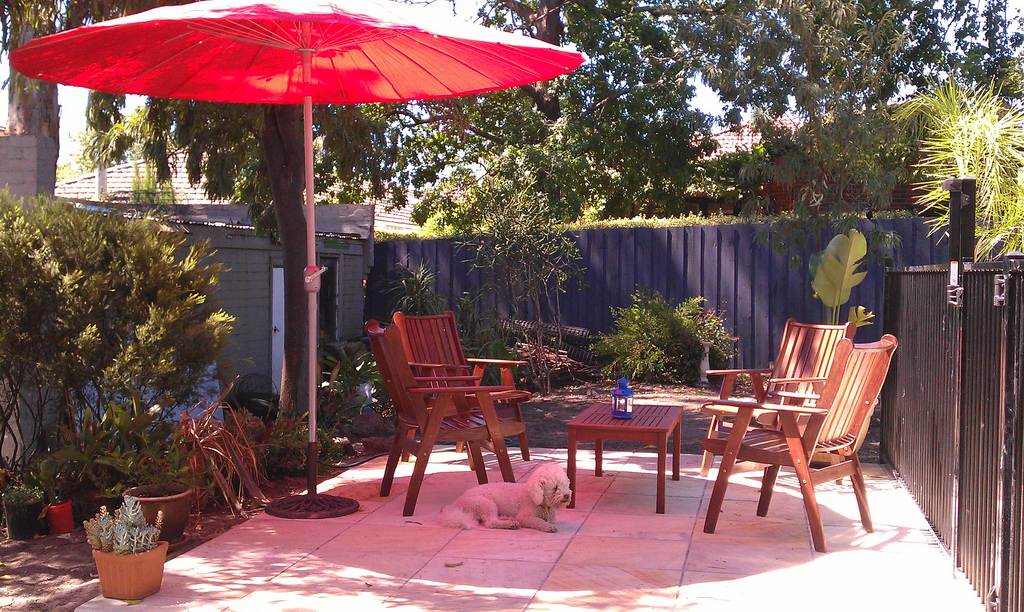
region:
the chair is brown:
[785, 330, 903, 539]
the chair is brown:
[703, 304, 840, 400]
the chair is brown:
[394, 306, 525, 371]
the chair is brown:
[353, 314, 440, 523]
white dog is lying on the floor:
[429, 448, 592, 546]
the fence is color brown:
[887, 227, 1020, 610]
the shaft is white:
[261, 30, 367, 524]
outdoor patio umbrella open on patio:
[8, 2, 590, 528]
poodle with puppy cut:
[439, 458, 580, 538]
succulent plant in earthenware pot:
[79, 490, 174, 602]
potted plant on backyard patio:
[88, 360, 199, 545]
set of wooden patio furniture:
[363, 303, 899, 554]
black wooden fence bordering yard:
[375, 212, 952, 389]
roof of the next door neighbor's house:
[604, 92, 937, 191]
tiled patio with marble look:
[69, 437, 975, 609]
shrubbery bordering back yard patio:
[3, 193, 235, 487]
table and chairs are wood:
[370, 302, 893, 540]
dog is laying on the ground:
[446, 459, 573, 539]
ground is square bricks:
[61, 456, 988, 606]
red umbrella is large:
[0, 0, 588, 525]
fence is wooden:
[370, 216, 950, 388]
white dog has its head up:
[441, 463, 568, 527]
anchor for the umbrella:
[264, 438, 354, 519]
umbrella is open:
[2, 1, 582, 296]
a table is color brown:
[555, 388, 693, 518]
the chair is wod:
[354, 311, 520, 528]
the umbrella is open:
[3, 8, 589, 142]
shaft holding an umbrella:
[291, 42, 336, 520]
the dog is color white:
[442, 442, 583, 548]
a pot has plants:
[73, 483, 176, 610]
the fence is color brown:
[865, 232, 1022, 610]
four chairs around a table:
[350, 274, 913, 559]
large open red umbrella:
[52, 4, 561, 132]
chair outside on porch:
[356, 288, 534, 489]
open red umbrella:
[14, 7, 577, 132]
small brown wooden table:
[560, 382, 684, 503]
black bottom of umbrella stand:
[266, 436, 358, 525]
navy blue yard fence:
[377, 208, 921, 417]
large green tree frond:
[787, 196, 877, 313]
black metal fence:
[874, 195, 1012, 608]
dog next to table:
[441, 462, 581, 545]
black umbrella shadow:
[264, 417, 843, 604]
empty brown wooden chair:
[712, 323, 912, 555]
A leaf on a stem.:
[803, 220, 871, 306]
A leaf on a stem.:
[815, 140, 826, 163]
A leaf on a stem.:
[130, 394, 141, 421]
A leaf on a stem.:
[101, 396, 117, 428]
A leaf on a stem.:
[85, 408, 98, 443]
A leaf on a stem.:
[37, 454, 53, 478]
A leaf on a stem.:
[452, 236, 466, 247]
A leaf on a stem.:
[454, 196, 468, 212]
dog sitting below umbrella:
[434, 439, 575, 547]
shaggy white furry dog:
[435, 462, 582, 552]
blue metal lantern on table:
[607, 372, 643, 426]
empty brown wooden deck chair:
[740, 329, 897, 538]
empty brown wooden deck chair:
[359, 312, 512, 516]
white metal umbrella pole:
[277, 42, 339, 461]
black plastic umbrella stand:
[267, 426, 365, 538]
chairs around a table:
[366, 291, 899, 535]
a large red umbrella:
[4, 3, 586, 124]